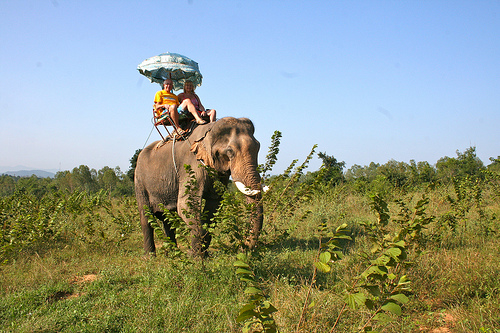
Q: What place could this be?
A: It is a field.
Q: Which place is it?
A: It is a field.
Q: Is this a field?
A: Yes, it is a field.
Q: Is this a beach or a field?
A: It is a field.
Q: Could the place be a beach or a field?
A: It is a field.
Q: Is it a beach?
A: No, it is a field.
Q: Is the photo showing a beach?
A: No, the picture is showing a field.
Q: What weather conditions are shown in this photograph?
A: It is cloudless.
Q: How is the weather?
A: It is cloudless.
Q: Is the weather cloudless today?
A: Yes, it is cloudless.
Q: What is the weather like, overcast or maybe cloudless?
A: It is cloudless.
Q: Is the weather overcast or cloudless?
A: It is cloudless.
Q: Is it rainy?
A: No, it is cloudless.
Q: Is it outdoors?
A: Yes, it is outdoors.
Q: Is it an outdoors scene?
A: Yes, it is outdoors.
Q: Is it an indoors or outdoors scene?
A: It is outdoors.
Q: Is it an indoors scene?
A: No, it is outdoors.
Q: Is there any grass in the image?
A: Yes, there is grass.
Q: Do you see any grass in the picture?
A: Yes, there is grass.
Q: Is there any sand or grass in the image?
A: Yes, there is grass.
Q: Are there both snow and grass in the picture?
A: No, there is grass but no snow.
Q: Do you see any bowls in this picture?
A: No, there are no bowls.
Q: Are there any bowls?
A: No, there are no bowls.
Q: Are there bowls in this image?
A: No, there are no bowls.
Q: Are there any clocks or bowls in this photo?
A: No, there are no bowls or clocks.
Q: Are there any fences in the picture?
A: No, there are no fences.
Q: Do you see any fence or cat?
A: No, there are no fences or cats.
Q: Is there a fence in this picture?
A: No, there are no fences.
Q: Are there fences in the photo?
A: No, there are no fences.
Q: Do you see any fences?
A: No, there are no fences.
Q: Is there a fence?
A: No, there are no fences.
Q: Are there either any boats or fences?
A: No, there are no fences or boats.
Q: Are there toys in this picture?
A: No, there are no toys.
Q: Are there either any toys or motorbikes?
A: No, there are no toys or motorbikes.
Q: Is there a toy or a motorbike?
A: No, there are no toys or motorcycles.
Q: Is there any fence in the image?
A: No, there are no fences.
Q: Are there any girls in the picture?
A: No, there are no girls.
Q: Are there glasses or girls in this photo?
A: No, there are no girls or glasses.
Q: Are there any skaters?
A: No, there are no skaters.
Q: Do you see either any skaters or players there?
A: No, there are no skaters or players.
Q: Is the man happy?
A: Yes, the man is happy.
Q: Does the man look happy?
A: Yes, the man is happy.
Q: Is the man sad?
A: No, the man is happy.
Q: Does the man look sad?
A: No, the man is happy.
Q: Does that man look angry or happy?
A: The man is happy.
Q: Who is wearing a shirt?
A: The man is wearing a shirt.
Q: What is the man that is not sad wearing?
A: The man is wearing a shirt.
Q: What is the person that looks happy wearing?
A: The man is wearing a shirt.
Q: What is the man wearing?
A: The man is wearing a shirt.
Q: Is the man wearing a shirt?
A: Yes, the man is wearing a shirt.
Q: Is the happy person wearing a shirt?
A: Yes, the man is wearing a shirt.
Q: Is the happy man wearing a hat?
A: No, the man is wearing a shirt.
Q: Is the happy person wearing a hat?
A: No, the man is wearing a shirt.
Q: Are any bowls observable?
A: No, there are no bowls.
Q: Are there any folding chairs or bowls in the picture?
A: No, there are no bowls or folding chairs.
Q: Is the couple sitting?
A: Yes, the couple is sitting.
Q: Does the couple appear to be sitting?
A: Yes, the couple is sitting.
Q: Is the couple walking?
A: No, the couple is sitting.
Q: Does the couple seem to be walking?
A: No, the couple is sitting.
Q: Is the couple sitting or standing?
A: The couple is sitting.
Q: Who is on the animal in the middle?
A: The couple is on the elephant.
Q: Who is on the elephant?
A: The couple is on the elephant.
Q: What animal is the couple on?
A: The couple is on the elephant.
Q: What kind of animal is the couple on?
A: The couple is on the elephant.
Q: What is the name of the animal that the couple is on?
A: The animal is an elephant.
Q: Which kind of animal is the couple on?
A: The couple is on the elephant.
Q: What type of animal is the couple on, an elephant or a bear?
A: The couple is on an elephant.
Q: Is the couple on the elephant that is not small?
A: Yes, the couple is on the elephant.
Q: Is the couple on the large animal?
A: Yes, the couple is on the elephant.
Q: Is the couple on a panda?
A: No, the couple is on the elephant.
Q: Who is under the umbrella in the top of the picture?
A: The couple is under the umbrella.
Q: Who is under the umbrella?
A: The couple is under the umbrella.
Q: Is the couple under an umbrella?
A: Yes, the couple is under an umbrella.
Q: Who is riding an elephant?
A: The couple is riding an elephant.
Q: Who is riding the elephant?
A: The couple is riding an elephant.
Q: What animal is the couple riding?
A: The couple is riding an elephant.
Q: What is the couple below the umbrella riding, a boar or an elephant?
A: The couple is riding an elephant.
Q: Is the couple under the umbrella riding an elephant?
A: Yes, the couple is riding an elephant.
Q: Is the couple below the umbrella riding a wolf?
A: No, the couple is riding an elephant.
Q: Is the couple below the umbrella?
A: Yes, the couple is below the umbrella.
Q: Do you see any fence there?
A: No, there are no fences.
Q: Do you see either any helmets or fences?
A: No, there are no fences or helmets.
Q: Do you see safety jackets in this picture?
A: No, there are no safety jackets.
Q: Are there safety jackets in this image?
A: No, there are no safety jackets.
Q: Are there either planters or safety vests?
A: No, there are no safety vests or planters.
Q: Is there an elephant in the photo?
A: Yes, there is an elephant.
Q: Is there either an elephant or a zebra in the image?
A: Yes, there is an elephant.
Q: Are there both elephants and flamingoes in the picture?
A: No, there is an elephant but no flamingoes.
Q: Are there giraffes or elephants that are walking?
A: Yes, the elephant is walking.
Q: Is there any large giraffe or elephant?
A: Yes, there is a large elephant.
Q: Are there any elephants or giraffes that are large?
A: Yes, the elephant is large.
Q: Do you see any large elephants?
A: Yes, there is a large elephant.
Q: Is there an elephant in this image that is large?
A: Yes, there is an elephant that is large.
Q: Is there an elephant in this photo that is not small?
A: Yes, there is a large elephant.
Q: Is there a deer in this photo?
A: No, there is no deer.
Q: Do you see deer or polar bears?
A: No, there are no deer or polar bears.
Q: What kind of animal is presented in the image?
A: The animal is an elephant.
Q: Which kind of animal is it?
A: The animal is an elephant.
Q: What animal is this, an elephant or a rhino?
A: That is an elephant.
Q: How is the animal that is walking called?
A: The animal is an elephant.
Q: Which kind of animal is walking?
A: The animal is an elephant.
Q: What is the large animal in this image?
A: The animal is an elephant.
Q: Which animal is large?
A: The animal is an elephant.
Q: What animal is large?
A: The animal is an elephant.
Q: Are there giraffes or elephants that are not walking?
A: No, there is an elephant but it is walking.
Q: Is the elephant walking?
A: Yes, the elephant is walking.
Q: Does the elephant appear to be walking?
A: Yes, the elephant is walking.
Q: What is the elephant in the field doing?
A: The elephant is walking.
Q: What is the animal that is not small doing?
A: The elephant is walking.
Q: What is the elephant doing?
A: The elephant is walking.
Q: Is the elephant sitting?
A: No, the elephant is walking.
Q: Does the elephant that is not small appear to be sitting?
A: No, the elephant is walking.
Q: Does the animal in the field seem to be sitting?
A: No, the elephant is walking.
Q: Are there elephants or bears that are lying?
A: No, there is an elephant but it is walking.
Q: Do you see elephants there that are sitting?
A: No, there is an elephant but it is walking.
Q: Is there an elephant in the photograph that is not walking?
A: No, there is an elephant but it is walking.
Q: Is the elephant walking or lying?
A: The elephant is walking.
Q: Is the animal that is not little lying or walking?
A: The elephant is walking.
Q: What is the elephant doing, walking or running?
A: The elephant is walking.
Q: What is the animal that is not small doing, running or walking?
A: The elephant is walking.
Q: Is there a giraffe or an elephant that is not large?
A: No, there is an elephant but it is large.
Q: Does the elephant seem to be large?
A: Yes, the elephant is large.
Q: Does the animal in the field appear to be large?
A: Yes, the elephant is large.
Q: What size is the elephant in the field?
A: The elephant is large.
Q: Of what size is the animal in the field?
A: The elephant is large.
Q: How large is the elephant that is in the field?
A: The elephant is large.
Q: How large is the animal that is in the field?
A: The elephant is large.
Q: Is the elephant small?
A: No, the elephant is large.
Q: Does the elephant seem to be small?
A: No, the elephant is large.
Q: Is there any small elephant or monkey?
A: No, there is an elephant but it is large.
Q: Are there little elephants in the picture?
A: No, there is an elephant but it is large.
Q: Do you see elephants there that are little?
A: No, there is an elephant but it is large.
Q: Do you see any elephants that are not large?
A: No, there is an elephant but it is large.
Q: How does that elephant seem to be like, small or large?
A: The elephant is large.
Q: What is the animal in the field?
A: The animal is an elephant.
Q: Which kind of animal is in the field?
A: The animal is an elephant.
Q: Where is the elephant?
A: The elephant is in the field.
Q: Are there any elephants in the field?
A: Yes, there is an elephant in the field.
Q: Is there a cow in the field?
A: No, there is an elephant in the field.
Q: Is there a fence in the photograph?
A: No, there are no fences.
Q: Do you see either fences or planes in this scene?
A: No, there are no fences or planes.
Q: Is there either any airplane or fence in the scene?
A: No, there are no fences or airplanes.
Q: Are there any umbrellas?
A: Yes, there is an umbrella.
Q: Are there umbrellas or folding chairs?
A: Yes, there is an umbrella.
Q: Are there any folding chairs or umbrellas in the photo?
A: Yes, there is an umbrella.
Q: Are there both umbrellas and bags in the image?
A: No, there is an umbrella but no bags.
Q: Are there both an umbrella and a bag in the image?
A: No, there is an umbrella but no bags.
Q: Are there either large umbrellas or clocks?
A: Yes, there is a large umbrella.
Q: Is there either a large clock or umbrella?
A: Yes, there is a large umbrella.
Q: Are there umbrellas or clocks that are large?
A: Yes, the umbrella is large.